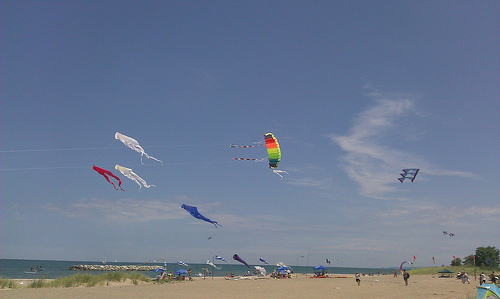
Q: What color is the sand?
A: Brown.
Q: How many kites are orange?
A: Zero.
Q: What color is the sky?
A: Blue.